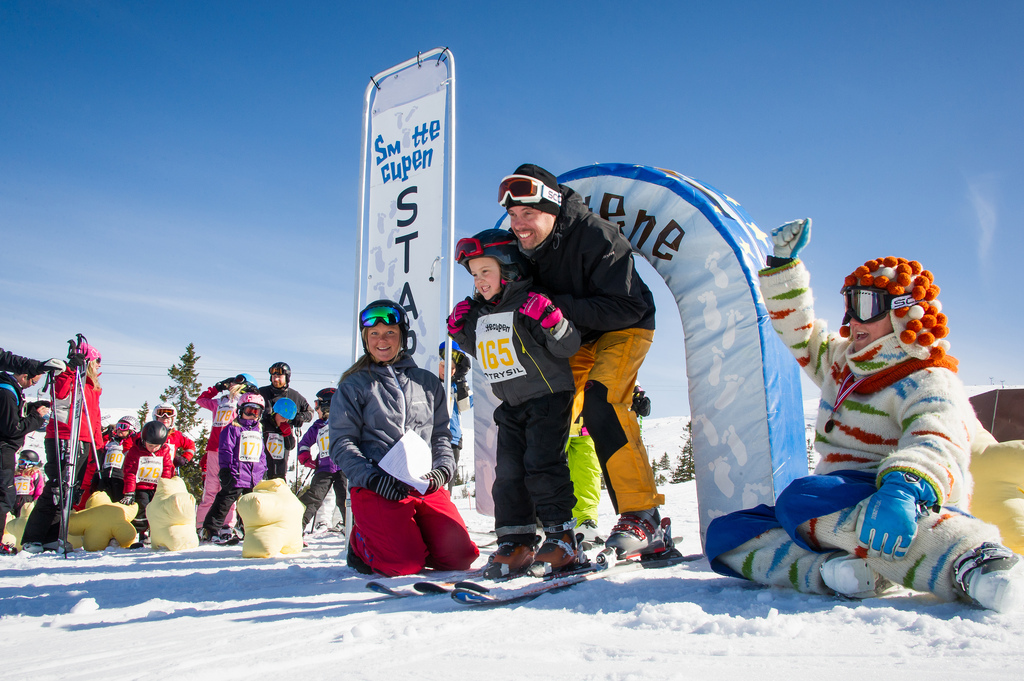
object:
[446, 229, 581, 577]
girl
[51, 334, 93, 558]
camera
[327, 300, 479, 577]
woman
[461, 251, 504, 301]
girl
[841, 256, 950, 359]
hat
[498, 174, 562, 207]
goggles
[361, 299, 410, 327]
goggles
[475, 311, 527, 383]
sign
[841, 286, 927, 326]
goggles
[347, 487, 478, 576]
pants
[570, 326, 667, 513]
pants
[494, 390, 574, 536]
pants